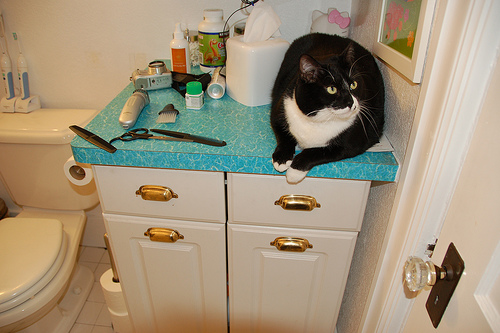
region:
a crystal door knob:
[393, 245, 464, 309]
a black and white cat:
[256, 19, 396, 205]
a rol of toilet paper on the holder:
[59, 145, 103, 198]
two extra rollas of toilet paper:
[87, 260, 132, 331]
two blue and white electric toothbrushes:
[1, 28, 38, 122]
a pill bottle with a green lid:
[181, 78, 213, 113]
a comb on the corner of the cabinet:
[65, 120, 122, 163]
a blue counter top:
[62, 58, 402, 179]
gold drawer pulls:
[123, 177, 326, 274]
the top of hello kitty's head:
[300, 8, 366, 48]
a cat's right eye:
[325, 83, 337, 95]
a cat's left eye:
[349, 80, 356, 89]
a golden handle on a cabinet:
[134, 182, 177, 202]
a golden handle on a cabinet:
[273, 192, 321, 211]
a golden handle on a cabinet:
[142, 225, 182, 242]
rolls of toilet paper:
[95, 233, 130, 332]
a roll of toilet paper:
[62, 152, 93, 186]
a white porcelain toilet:
[0, 108, 99, 331]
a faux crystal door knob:
[402, 255, 428, 295]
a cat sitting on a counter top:
[270, 33, 396, 186]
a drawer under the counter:
[93, 163, 228, 225]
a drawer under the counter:
[226, 172, 368, 231]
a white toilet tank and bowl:
[0, 108, 97, 332]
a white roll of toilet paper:
[66, 156, 89, 184]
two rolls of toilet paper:
[101, 268, 131, 331]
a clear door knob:
[403, 253, 456, 298]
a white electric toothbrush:
[10, 30, 39, 115]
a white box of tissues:
[222, 5, 291, 107]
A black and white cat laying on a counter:
[268, 32, 387, 184]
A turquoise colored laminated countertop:
[69, 58, 400, 183]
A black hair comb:
[66, 122, 118, 154]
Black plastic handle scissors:
[106, 125, 195, 145]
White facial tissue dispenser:
[223, 0, 291, 107]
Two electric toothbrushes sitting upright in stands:
[0, 29, 42, 113]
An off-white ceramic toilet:
[1, 106, 98, 332]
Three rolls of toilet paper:
[62, 152, 132, 332]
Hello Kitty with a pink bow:
[309, 7, 352, 34]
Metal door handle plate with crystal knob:
[401, 241, 466, 328]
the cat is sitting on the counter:
[259, 27, 390, 190]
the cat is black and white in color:
[252, 17, 399, 201]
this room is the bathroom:
[12, 10, 474, 317]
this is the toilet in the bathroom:
[4, 79, 93, 322]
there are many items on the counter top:
[91, 10, 303, 149]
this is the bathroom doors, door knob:
[394, 248, 441, 305]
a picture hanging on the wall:
[376, 1, 436, 68]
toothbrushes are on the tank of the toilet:
[0, 21, 40, 132]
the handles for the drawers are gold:
[138, 183, 338, 213]